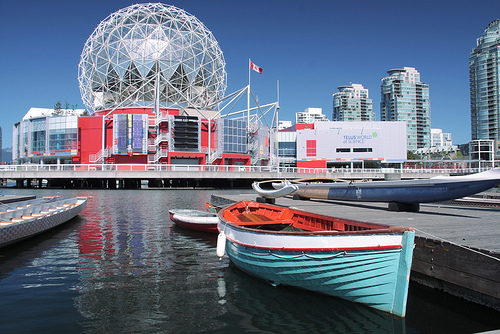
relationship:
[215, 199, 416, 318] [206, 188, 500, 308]
boat next to dock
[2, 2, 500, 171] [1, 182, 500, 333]
city next to water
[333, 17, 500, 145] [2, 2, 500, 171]
buildings are in city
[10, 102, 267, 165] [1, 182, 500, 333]
building in front of water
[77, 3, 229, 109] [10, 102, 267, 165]
circle on top of building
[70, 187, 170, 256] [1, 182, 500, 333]
reflection in water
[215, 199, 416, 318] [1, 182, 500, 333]
boat in water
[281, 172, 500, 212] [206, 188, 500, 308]
boat on dock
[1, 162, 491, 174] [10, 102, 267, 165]
railing in front of building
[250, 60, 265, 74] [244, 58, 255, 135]
flag on a pole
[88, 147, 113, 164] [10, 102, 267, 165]
staircase on side of building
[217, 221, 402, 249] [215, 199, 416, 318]
stripe on boat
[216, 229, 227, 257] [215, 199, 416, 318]
flotation device on side of boat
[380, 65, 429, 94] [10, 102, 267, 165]
top of a building